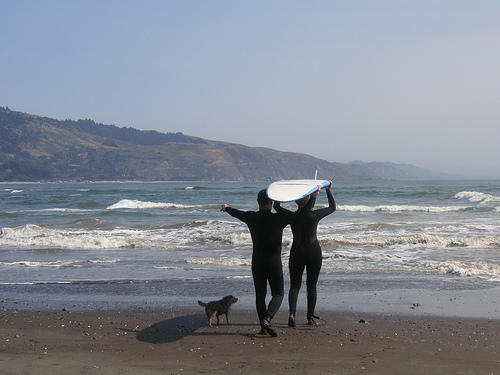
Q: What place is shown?
A: It is an ocean.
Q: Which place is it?
A: It is an ocean.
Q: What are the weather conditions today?
A: It is clear.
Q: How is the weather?
A: It is clear.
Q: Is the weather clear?
A: Yes, it is clear.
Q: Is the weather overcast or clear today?
A: It is clear.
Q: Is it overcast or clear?
A: It is clear.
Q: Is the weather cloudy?
A: No, it is clear.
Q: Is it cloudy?
A: No, it is clear.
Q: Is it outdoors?
A: Yes, it is outdoors.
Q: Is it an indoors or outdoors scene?
A: It is outdoors.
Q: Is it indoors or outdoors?
A: It is outdoors.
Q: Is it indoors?
A: No, it is outdoors.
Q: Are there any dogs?
A: Yes, there is a dog.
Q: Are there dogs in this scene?
A: Yes, there is a dog.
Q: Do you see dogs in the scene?
A: Yes, there is a dog.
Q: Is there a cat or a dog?
A: Yes, there is a dog.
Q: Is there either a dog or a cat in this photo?
A: Yes, there is a dog.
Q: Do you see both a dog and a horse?
A: No, there is a dog but no horses.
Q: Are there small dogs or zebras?
A: Yes, there is a small dog.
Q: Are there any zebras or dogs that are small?
A: Yes, the dog is small.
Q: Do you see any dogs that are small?
A: Yes, there is a small dog.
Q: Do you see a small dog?
A: Yes, there is a small dog.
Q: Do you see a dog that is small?
A: Yes, there is a dog that is small.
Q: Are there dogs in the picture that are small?
A: Yes, there is a dog that is small.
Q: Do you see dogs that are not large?
A: Yes, there is a small dog.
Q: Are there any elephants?
A: No, there are no elephants.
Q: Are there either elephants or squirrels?
A: No, there are no elephants or squirrels.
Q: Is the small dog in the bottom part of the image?
A: Yes, the dog is in the bottom of the image.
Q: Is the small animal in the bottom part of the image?
A: Yes, the dog is in the bottom of the image.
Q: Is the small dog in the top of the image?
A: No, the dog is in the bottom of the image.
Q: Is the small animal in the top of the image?
A: No, the dog is in the bottom of the image.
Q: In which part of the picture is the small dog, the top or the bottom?
A: The dog is in the bottom of the image.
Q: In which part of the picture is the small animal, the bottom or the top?
A: The dog is in the bottom of the image.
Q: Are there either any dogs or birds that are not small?
A: No, there is a dog but it is small.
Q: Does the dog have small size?
A: Yes, the dog is small.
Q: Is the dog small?
A: Yes, the dog is small.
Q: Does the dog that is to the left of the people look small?
A: Yes, the dog is small.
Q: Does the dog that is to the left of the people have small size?
A: Yes, the dog is small.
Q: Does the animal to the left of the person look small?
A: Yes, the dog is small.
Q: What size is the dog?
A: The dog is small.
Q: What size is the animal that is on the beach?
A: The dog is small.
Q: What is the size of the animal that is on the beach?
A: The dog is small.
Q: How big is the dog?
A: The dog is small.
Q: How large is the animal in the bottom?
A: The dog is small.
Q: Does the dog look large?
A: No, the dog is small.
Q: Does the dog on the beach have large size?
A: No, the dog is small.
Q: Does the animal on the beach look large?
A: No, the dog is small.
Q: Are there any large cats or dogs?
A: No, there is a dog but it is small.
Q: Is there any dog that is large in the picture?
A: No, there is a dog but it is small.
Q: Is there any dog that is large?
A: No, there is a dog but it is small.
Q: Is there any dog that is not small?
A: No, there is a dog but it is small.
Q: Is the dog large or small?
A: The dog is small.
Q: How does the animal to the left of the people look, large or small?
A: The dog is small.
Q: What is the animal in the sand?
A: The animal is a dog.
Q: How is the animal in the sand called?
A: The animal is a dog.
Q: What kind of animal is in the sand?
A: The animal is a dog.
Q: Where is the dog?
A: The dog is in the sand.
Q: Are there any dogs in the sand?
A: Yes, there is a dog in the sand.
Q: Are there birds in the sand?
A: No, there is a dog in the sand.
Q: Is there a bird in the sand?
A: No, there is a dog in the sand.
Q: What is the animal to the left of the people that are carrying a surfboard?
A: The animal is a dog.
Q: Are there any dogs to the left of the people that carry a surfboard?
A: Yes, there is a dog to the left of the people.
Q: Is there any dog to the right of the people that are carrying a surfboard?
A: No, the dog is to the left of the people.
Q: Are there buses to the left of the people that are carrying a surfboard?
A: No, there is a dog to the left of the people.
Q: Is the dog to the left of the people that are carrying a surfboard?
A: Yes, the dog is to the left of the people.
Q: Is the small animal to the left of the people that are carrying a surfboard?
A: Yes, the dog is to the left of the people.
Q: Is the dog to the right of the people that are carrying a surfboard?
A: No, the dog is to the left of the people.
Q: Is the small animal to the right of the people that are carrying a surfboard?
A: No, the dog is to the left of the people.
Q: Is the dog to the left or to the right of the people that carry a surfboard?
A: The dog is to the left of the people.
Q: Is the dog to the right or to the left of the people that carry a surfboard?
A: The dog is to the left of the people.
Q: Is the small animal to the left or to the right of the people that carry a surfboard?
A: The dog is to the left of the people.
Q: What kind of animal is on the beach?
A: The animal is a dog.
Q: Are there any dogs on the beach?
A: Yes, there is a dog on the beach.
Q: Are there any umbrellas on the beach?
A: No, there is a dog on the beach.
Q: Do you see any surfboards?
A: Yes, there is a surfboard.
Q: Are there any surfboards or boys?
A: Yes, there is a surfboard.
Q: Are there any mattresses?
A: No, there are no mattresses.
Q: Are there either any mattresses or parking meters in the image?
A: No, there are no mattresses or parking meters.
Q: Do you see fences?
A: No, there are no fences.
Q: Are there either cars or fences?
A: No, there are no fences or cars.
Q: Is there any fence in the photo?
A: No, there are no fences.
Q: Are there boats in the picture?
A: No, there are no boats.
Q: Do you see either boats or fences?
A: No, there are no boats or fences.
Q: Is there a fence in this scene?
A: No, there are no fences.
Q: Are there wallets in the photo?
A: No, there are no wallets.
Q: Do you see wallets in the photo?
A: No, there are no wallets.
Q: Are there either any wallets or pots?
A: No, there are no wallets or pots.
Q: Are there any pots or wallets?
A: No, there are no wallets or pots.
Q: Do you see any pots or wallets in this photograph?
A: No, there are no wallets or pots.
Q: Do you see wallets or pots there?
A: No, there are no wallets or pots.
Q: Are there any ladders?
A: No, there are no ladders.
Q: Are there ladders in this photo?
A: No, there are no ladders.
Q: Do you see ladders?
A: No, there are no ladders.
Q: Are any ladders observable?
A: No, there are no ladders.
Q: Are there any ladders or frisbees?
A: No, there are no ladders or frisbees.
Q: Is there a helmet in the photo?
A: No, there are no helmets.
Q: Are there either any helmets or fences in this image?
A: No, there are no helmets or fences.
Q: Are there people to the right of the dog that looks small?
A: Yes, there is a person to the right of the dog.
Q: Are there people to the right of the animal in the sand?
A: Yes, there is a person to the right of the dog.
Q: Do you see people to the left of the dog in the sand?
A: No, the person is to the right of the dog.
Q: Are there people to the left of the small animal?
A: No, the person is to the right of the dog.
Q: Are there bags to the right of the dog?
A: No, there is a person to the right of the dog.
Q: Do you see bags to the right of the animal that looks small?
A: No, there is a person to the right of the dog.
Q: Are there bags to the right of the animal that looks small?
A: No, there is a person to the right of the dog.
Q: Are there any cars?
A: No, there are no cars.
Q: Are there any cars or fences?
A: No, there are no cars or fences.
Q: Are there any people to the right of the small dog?
A: Yes, there are people to the right of the dog.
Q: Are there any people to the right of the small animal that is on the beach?
A: Yes, there are people to the right of the dog.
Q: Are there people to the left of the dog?
A: No, the people are to the right of the dog.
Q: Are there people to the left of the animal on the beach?
A: No, the people are to the right of the dog.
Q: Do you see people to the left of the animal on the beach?
A: No, the people are to the right of the dog.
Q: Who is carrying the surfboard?
A: The people are carrying the surfboard.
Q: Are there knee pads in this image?
A: No, there are no knee pads.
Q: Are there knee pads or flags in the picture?
A: No, there are no knee pads or flags.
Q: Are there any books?
A: No, there are no books.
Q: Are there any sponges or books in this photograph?
A: No, there are no books or sponges.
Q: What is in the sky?
A: The clouds are in the sky.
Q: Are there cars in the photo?
A: No, there are no cars.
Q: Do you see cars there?
A: No, there are no cars.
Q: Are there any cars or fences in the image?
A: No, there are no cars or fences.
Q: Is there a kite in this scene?
A: No, there are no kites.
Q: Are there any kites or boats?
A: No, there are no kites or boats.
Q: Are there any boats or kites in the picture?
A: No, there are no kites or boats.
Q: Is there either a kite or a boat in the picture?
A: No, there are no kites or boats.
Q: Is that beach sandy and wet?
A: Yes, the beach is sandy and wet.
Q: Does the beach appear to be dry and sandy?
A: No, the beach is sandy but wet.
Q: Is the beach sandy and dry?
A: No, the beach is sandy but wet.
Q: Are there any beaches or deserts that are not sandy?
A: No, there is a beach but it is sandy.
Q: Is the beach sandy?
A: Yes, the beach is sandy.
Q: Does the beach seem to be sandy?
A: Yes, the beach is sandy.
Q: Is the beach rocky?
A: No, the beach is sandy.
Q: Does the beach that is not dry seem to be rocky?
A: No, the beach is sandy.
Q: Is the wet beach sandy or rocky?
A: The beach is sandy.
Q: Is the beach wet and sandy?
A: Yes, the beach is wet and sandy.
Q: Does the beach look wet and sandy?
A: Yes, the beach is wet and sandy.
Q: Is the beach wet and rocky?
A: No, the beach is wet but sandy.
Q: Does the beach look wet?
A: Yes, the beach is wet.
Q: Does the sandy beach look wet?
A: Yes, the beach is wet.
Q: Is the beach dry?
A: No, the beach is wet.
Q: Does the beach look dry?
A: No, the beach is wet.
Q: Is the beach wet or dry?
A: The beach is wet.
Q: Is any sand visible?
A: Yes, there is sand.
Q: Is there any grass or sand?
A: Yes, there is sand.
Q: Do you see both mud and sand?
A: No, there is sand but no mud.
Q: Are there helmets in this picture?
A: No, there are no helmets.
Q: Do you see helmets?
A: No, there are no helmets.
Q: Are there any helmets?
A: No, there are no helmets.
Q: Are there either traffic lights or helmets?
A: No, there are no helmets or traffic lights.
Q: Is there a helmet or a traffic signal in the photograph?
A: No, there are no helmets or traffic lights.